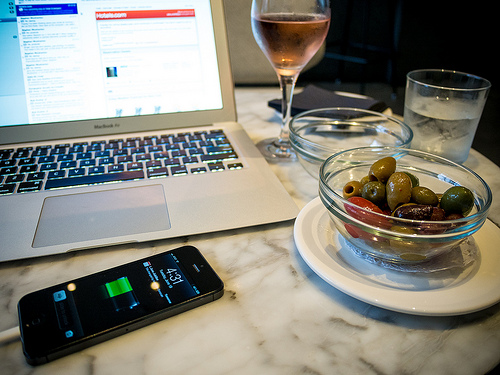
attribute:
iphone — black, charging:
[12, 242, 230, 366]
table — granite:
[15, 247, 457, 371]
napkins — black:
[265, 71, 385, 122]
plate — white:
[291, 190, 500, 315]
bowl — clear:
[318, 139, 492, 247]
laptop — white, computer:
[0, 1, 314, 265]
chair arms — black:
[337, 41, 388, 92]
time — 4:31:
[161, 261, 186, 293]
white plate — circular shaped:
[367, 281, 475, 320]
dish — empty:
[284, 102, 413, 156]